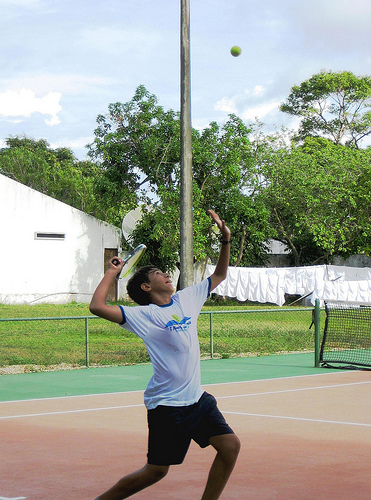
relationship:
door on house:
[100, 244, 120, 303] [6, 165, 140, 308]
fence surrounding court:
[0, 305, 321, 374] [0, 349, 368, 497]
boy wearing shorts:
[86, 207, 242, 500] [133, 391, 232, 465]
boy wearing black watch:
[86, 207, 242, 500] [222, 238, 233, 244]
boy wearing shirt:
[86, 207, 242, 500] [117, 279, 210, 407]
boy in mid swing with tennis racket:
[86, 207, 242, 500] [110, 242, 147, 280]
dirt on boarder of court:
[0, 346, 366, 373] [0, 349, 368, 497]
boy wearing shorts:
[86, 207, 242, 500] [130, 384, 227, 473]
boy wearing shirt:
[88, 207, 242, 498] [113, 276, 215, 413]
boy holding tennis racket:
[88, 207, 242, 498] [104, 241, 149, 278]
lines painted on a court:
[236, 385, 323, 431] [0, 306, 369, 500]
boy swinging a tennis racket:
[88, 207, 242, 498] [109, 242, 147, 277]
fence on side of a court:
[0, 305, 321, 374] [0, 349, 368, 497]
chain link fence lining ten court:
[10, 335, 99, 408] [7, 325, 366, 500]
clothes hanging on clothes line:
[201, 260, 367, 312] [209, 263, 366, 292]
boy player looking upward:
[86, 207, 242, 500] [81, 262, 232, 336]